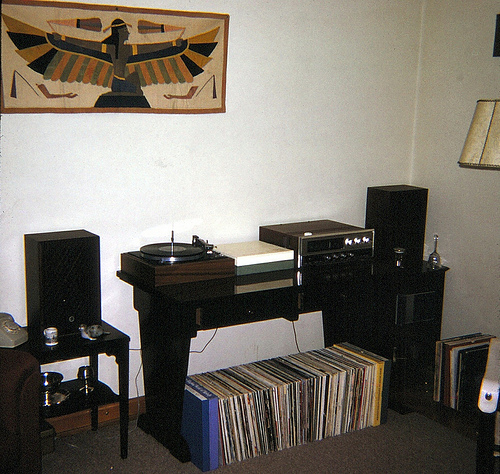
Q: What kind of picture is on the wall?
A: Egyptian picture.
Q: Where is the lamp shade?
A: On the right.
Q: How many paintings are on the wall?
A: 1.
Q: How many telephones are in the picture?
A: 1.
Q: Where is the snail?
A: On the table.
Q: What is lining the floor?
A: Records.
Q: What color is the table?
A: Black.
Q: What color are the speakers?
A: Black.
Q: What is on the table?
A: Stereo.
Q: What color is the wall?
A: White.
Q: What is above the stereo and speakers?
A: Picture.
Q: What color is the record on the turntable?
A: Black.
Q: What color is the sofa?
A: Brown.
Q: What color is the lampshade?
A: White.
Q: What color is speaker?
A: Jet black.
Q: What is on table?
A: Black speaker.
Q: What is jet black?
A: Speaker.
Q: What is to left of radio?
A: Black speaker.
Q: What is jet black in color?
A: Speaker.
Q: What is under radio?
A: Collection of record albums.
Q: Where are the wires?
A: Against a wall.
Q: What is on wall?
A: Picture hanging.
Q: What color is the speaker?
A: Black.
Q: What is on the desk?
A: Radio.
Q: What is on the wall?
A: Painting.